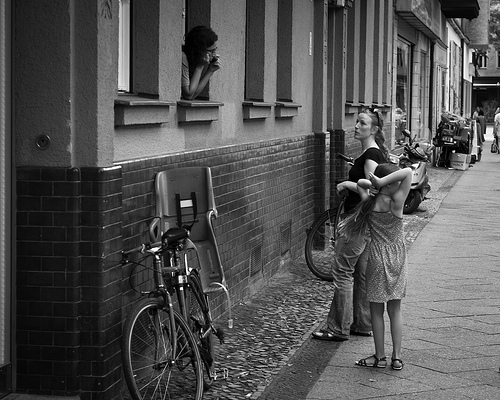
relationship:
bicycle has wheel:
[116, 226, 218, 400] [126, 299, 208, 399]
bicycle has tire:
[293, 153, 397, 282] [302, 211, 343, 282]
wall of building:
[225, 171, 283, 239] [24, 9, 470, 370]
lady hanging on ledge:
[178, 23, 224, 102] [156, 80, 306, 132]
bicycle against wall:
[116, 226, 218, 400] [79, 99, 341, 364]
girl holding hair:
[351, 161, 415, 371] [352, 160, 398, 232]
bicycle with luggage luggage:
[116, 226, 218, 400] [434, 108, 464, 130]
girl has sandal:
[356, 163, 413, 376] [352, 357, 391, 378]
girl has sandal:
[356, 163, 413, 376] [384, 349, 408, 376]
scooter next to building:
[399, 128, 437, 214] [6, 0, 488, 398]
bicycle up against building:
[116, 210, 238, 397] [24, 9, 470, 370]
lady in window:
[172, 20, 230, 107] [174, 2, 224, 121]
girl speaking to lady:
[351, 161, 415, 371] [172, 20, 230, 107]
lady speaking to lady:
[313, 110, 394, 344] [172, 20, 230, 107]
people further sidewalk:
[468, 102, 498, 154] [291, 97, 498, 392]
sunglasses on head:
[364, 98, 381, 117] [353, 92, 386, 148]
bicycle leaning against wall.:
[116, 226, 218, 400] [57, 140, 330, 373]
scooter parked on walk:
[394, 130, 431, 214] [115, 164, 467, 398]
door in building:
[397, 55, 413, 154] [73, 2, 486, 156]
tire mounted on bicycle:
[302, 211, 344, 293] [301, 150, 356, 281]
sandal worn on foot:
[354, 354, 388, 370] [355, 354, 387, 368]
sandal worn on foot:
[390, 357, 402, 370] [389, 359, 402, 369]